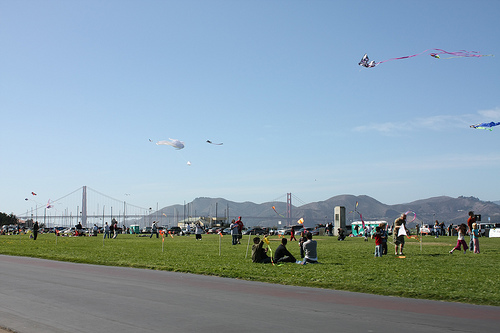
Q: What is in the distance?
A: Small mountains in the landscape.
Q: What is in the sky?
A: Kites flying in the air.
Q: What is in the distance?
A: Gray mountains in the distance.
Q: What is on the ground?
A: Green grass on the ground.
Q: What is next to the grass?
A: Street next to the field of grass.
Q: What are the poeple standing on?
A: A green grassy field.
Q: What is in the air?
A: A long suspension bridge in distance.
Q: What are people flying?
A: Kites.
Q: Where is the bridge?
A: In distance.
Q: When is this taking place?
A: Daytime.